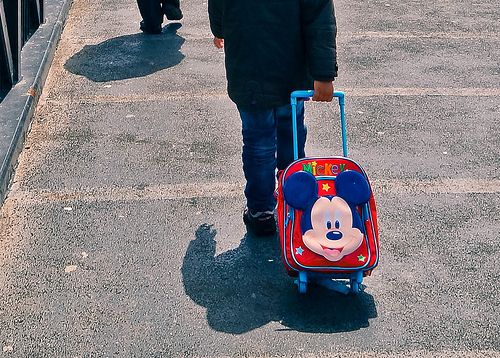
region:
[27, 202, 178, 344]
Gray pavement on the ground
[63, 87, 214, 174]
Gray pavement on the ground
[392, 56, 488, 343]
Gray pavement on the ground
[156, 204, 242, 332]
Shadow of person rolling backpack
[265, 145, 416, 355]
Mickey Mouse rolling backpack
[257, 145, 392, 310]
Mickey Mouse rolling backpack with blue wheels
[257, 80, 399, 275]
Mickey Mouse rolling backpack with blue handle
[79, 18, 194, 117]
Shadow of person walking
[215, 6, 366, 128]
Person pulling backpack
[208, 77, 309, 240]
Blue pants of person pulling backpack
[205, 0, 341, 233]
a boy is walking in the street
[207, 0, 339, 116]
the boy is wearing a blue down jacket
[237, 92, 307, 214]
the boy is wearing blue jeans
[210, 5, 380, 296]
the boy is pulling a suitcase on wheels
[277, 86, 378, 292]
the suit case has mickey on it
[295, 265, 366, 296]
the suit case has blue wheels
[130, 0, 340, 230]
a man is walking in front of the boy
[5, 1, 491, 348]
the pavement has white lines on it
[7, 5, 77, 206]
an iron fence is on the curb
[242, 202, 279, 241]
the boy has black sneakers on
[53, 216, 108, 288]
small spots on ground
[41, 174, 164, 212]
faint white line on ground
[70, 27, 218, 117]
shadow of person on ground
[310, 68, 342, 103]
man's hand on bag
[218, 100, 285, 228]
wrinkled blue jeans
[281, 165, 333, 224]
large blue ears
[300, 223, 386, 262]
large grin on Mickey Mouse's face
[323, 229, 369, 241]
shiny black nose on bag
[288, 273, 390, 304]
blue wheels on the bag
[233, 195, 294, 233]
white edge of black sneaker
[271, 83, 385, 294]
blue and red Mickey Mouse carry all luggage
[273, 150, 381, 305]
red case with Mickey Mouse face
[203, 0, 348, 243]
person pulling luggage wearing black shirt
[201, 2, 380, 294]
person pulling luggage wearing jeans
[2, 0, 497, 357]
grey concrete sidewalk with white lines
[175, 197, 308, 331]
shadow of person on sidewalk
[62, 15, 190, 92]
shadow of background person on sidewalk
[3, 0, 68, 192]
black metal siding on sidewalk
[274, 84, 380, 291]
aqua blue wheels and arms on luggage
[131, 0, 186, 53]
person wearing black pants in background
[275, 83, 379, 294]
a Mickey Mouse rolling bag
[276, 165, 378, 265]
a mouse with big ears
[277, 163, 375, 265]
an illustration of a mouse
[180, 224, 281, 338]
the shadow of a boy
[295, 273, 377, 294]
light blue rollers on a bag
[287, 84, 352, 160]
light blue handle on a bag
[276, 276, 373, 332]
shadow of a bag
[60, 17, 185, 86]
shadow of a person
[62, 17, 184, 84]
shadow of a child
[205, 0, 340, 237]
a child walking